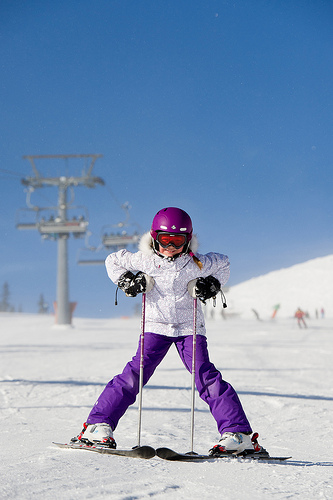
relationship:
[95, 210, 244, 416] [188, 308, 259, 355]
girl holding poles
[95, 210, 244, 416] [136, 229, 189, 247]
girl wearing goggles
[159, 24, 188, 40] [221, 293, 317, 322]
sky above people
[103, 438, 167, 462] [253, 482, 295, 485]
skis on ground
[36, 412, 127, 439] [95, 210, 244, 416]
foot of girl